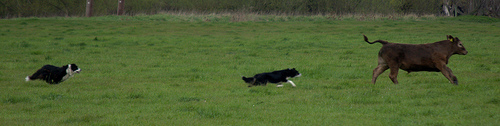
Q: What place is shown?
A: It is a field.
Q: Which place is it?
A: It is a field.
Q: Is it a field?
A: Yes, it is a field.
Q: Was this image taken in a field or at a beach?
A: It was taken at a field.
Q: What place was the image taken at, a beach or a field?
A: It was taken at a field.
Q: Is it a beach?
A: No, it is a field.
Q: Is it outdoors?
A: Yes, it is outdoors.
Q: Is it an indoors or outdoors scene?
A: It is outdoors.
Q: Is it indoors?
A: No, it is outdoors.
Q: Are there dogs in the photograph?
A: Yes, there is a dog.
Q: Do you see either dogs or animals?
A: Yes, there is a dog.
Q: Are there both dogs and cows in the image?
A: Yes, there are both a dog and a cow.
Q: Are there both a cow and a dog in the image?
A: Yes, there are both a dog and a cow.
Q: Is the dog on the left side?
A: Yes, the dog is on the left of the image.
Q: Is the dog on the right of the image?
A: No, the dog is on the left of the image.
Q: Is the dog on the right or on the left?
A: The dog is on the left of the image.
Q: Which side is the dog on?
A: The dog is on the left of the image.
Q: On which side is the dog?
A: The dog is on the left of the image.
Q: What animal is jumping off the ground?
A: The dog is jumping off the ground.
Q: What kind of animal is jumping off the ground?
A: The animal is a dog.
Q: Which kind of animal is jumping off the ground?
A: The animal is a dog.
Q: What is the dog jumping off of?
A: The dog is jumping off the ground.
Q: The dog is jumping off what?
A: The dog is jumping off the ground.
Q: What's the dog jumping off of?
A: The dog is jumping off the ground.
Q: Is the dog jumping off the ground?
A: Yes, the dog is jumping off the ground.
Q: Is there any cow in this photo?
A: Yes, there is a cow.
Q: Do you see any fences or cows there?
A: Yes, there is a cow.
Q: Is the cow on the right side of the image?
A: Yes, the cow is on the right of the image.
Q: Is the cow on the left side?
A: No, the cow is on the right of the image.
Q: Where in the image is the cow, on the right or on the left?
A: The cow is on the right of the image.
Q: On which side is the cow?
A: The cow is on the right of the image.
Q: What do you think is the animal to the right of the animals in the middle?
A: The animal is a cow.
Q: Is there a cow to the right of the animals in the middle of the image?
A: Yes, there is a cow to the right of the animals.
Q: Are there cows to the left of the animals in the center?
A: No, the cow is to the right of the animals.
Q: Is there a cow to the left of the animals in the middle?
A: No, the cow is to the right of the animals.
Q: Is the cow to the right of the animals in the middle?
A: Yes, the cow is to the right of the animals.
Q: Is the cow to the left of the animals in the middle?
A: No, the cow is to the right of the animals.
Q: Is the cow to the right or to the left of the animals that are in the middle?
A: The cow is to the right of the animals.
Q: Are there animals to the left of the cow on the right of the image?
A: Yes, there are animals to the left of the cow.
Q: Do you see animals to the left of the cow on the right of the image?
A: Yes, there are animals to the left of the cow.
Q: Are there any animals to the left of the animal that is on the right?
A: Yes, there are animals to the left of the cow.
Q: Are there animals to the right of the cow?
A: No, the animals are to the left of the cow.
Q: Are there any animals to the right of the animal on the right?
A: No, the animals are to the left of the cow.